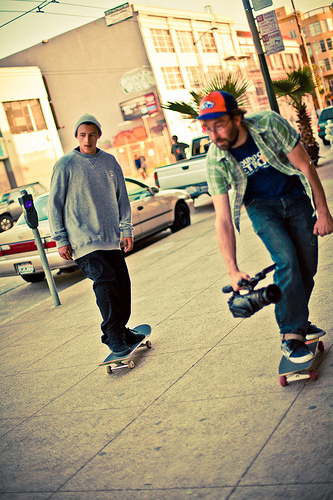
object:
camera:
[221, 265, 281, 318]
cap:
[194, 90, 237, 120]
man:
[201, 89, 333, 363]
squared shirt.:
[206, 111, 316, 233]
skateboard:
[100, 324, 153, 367]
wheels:
[318, 341, 324, 351]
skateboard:
[279, 335, 318, 377]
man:
[47, 114, 145, 357]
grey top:
[47, 146, 134, 248]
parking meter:
[18, 189, 38, 229]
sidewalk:
[0, 163, 333, 500]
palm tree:
[271, 66, 318, 163]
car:
[0, 178, 195, 282]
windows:
[150, 29, 217, 53]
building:
[0, 0, 333, 197]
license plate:
[18, 265, 33, 275]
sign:
[256, 10, 285, 56]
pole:
[243, 0, 281, 115]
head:
[200, 91, 240, 151]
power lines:
[0, 0, 137, 31]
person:
[171, 135, 190, 161]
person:
[134, 155, 147, 179]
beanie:
[74, 113, 103, 138]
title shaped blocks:
[1, 181, 333, 499]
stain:
[153, 446, 161, 451]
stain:
[199, 417, 207, 423]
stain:
[98, 450, 106, 456]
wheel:
[128, 360, 135, 368]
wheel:
[107, 365, 112, 373]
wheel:
[146, 340, 152, 349]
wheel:
[279, 376, 288, 387]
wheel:
[309, 369, 318, 380]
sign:
[104, 2, 133, 26]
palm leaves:
[267, 66, 319, 108]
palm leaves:
[160, 72, 253, 120]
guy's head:
[76, 115, 101, 152]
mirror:
[151, 186, 159, 193]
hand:
[123, 237, 133, 252]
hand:
[58, 245, 73, 261]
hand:
[313, 214, 333, 236]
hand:
[231, 272, 251, 292]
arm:
[273, 117, 329, 217]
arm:
[205, 156, 235, 275]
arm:
[48, 165, 66, 244]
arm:
[113, 172, 130, 229]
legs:
[247, 208, 318, 334]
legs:
[74, 256, 131, 335]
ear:
[234, 114, 241, 125]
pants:
[73, 249, 131, 343]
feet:
[281, 324, 327, 365]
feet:
[101, 328, 145, 356]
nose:
[212, 129, 219, 142]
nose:
[86, 136, 91, 142]